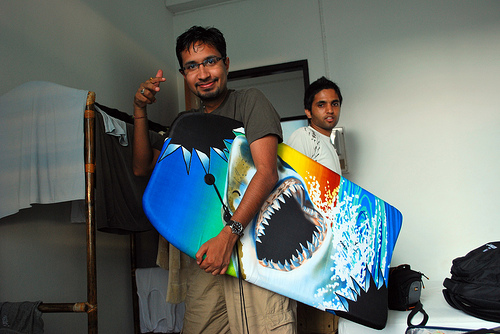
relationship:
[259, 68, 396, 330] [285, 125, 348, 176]
man wearing shirt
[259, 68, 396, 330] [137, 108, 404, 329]
man behind surfboard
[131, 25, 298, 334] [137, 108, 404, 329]
man holding surfboard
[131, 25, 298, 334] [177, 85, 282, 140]
man wearing t-shirt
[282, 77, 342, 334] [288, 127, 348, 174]
man in shirt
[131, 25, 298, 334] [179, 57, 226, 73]
man wears glasses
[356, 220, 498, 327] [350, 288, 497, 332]
luggage on bed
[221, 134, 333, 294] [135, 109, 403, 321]
shark on board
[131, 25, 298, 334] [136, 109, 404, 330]
man holds board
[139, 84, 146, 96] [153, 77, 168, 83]
ring on finger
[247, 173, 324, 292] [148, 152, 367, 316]
shark on surfboard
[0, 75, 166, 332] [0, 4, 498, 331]
wooden bed in bedroom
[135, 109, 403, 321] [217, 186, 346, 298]
board featuring picture of shark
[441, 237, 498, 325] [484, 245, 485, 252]
black bagpack with lettering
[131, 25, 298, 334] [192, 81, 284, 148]
man in shirt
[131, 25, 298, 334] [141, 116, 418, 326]
man holding surfboard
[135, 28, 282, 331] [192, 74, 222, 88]
man with moustache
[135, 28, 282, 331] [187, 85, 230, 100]
man with beard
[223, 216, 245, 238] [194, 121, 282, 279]
watch on arm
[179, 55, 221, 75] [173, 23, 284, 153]
glasses on man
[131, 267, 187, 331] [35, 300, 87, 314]
shirt on rail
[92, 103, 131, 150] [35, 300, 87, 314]
shirt on rail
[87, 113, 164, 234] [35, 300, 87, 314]
shirt on rail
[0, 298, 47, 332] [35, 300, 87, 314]
shirt on rail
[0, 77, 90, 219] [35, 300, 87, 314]
shirt on rail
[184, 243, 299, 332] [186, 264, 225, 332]
pants colored khaki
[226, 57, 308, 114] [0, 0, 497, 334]
doorway constructed in bedroom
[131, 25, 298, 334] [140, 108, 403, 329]
man holding surf board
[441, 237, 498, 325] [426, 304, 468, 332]
black bagpack on top of table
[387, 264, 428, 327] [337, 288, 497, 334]
luggage on top of bed